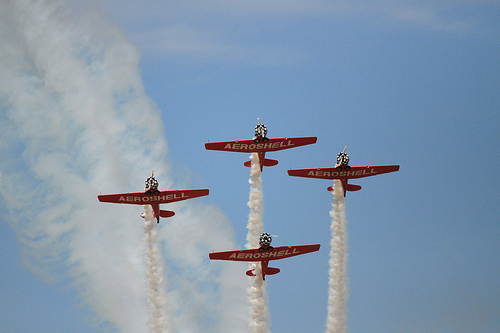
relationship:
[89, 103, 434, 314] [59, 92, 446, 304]
plains in formation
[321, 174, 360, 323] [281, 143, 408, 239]
trail behind plane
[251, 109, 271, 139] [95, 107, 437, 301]
propeller on plane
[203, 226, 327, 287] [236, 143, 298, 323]
airplane through smoke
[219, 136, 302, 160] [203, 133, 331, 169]
aeroshell on wings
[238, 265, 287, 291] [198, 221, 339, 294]
tail on airplane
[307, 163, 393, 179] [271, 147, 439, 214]
wings on plane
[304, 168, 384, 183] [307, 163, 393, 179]
letters on wings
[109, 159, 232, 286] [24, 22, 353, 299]
plane in sky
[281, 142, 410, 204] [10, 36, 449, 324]
plane in sky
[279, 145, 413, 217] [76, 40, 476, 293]
plane in sky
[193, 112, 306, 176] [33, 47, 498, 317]
plane in sky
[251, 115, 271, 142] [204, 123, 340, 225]
propeller on plane